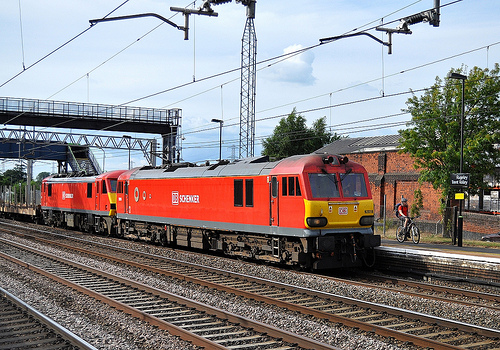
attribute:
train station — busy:
[97, 101, 471, 264]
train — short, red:
[38, 149, 379, 272]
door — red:
[267, 174, 278, 226]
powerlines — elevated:
[5, 0, 492, 159]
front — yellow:
[301, 194, 377, 229]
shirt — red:
[396, 205, 406, 217]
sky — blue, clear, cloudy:
[1, 22, 458, 159]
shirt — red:
[400, 210, 407, 216]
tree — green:
[395, 62, 499, 238]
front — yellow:
[303, 200, 375, 227]